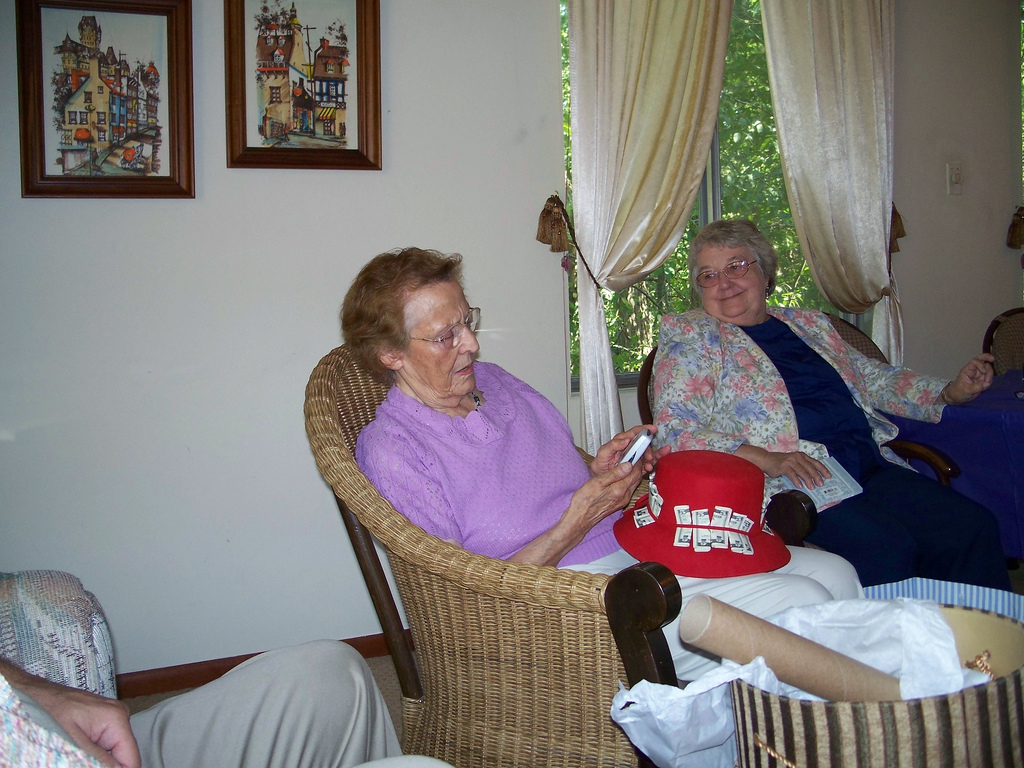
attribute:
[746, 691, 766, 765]
stripe — dark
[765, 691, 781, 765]
stripe — dark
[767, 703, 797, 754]
stripe — dark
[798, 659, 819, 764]
stripe — dark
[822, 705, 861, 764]
stripe — dark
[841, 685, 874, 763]
stripe — dark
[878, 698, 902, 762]
stripe — dark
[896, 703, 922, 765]
stripe — dark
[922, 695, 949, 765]
stripe — dark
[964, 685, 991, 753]
stripe — dark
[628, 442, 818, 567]
hat — bright red